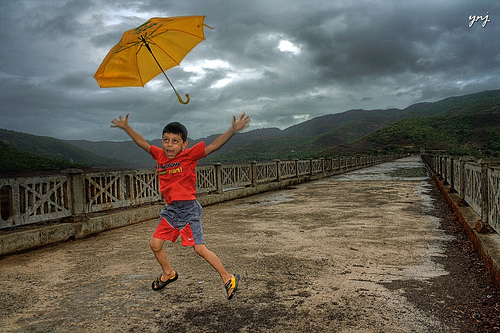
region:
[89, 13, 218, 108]
Yellow umbrella in the air.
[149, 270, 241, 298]
Grey and yellow sandals.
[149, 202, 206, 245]
Grey and red shorts.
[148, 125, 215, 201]
Boy wearing a red t-shirt with a design on the front.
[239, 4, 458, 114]
Ominous dark clouds.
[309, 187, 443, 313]
Rough well-traveled road?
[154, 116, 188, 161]
Safety railing near road.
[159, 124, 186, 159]
A young boy showing lots of emotions.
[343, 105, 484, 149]
Mountians and rolling hills.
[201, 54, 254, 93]
Sunlight peeping through clouds.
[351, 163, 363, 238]
part of a path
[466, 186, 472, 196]
part of a rail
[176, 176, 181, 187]
part of a shirt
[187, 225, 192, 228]
part of a short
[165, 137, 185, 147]
face of a boy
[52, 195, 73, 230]
part of a fence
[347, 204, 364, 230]
part of a bridge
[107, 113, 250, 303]
a boy jumping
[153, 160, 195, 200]
boy wearing a red shirt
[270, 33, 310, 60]
light in the sky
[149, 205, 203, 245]
grey and red shorts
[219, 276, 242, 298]
boy is wearing yellow sandals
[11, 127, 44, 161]
grass on the mountain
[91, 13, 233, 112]
an umbrealla in the sky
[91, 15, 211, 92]
the umbrealla is yellow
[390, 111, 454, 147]
a mountain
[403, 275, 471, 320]
dirt on the ground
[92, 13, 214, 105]
bright yellow child sized umbrella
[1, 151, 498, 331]
long concrete bridge walkway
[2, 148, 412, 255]
slightly ornate safety fence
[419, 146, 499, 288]
slightly ornate safety fence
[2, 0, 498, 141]
very dark and stormy sky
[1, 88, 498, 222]
tree and grass covered hills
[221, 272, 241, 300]
yellow and black sandal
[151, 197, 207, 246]
grey and red kids shorts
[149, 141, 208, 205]
red shirt with printed logo on it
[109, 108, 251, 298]
little boy jumping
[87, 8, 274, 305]
boy throwing an umbrella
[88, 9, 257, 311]
a yellow umbrella over a boy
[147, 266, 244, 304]
yellow open shoes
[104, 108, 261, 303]
boy has red shirt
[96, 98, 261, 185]
two hands up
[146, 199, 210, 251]
a blue and red shorts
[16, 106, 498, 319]
a boy on a bridge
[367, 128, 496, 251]
rails on right side of bridge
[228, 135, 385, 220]
rails on left side of bridge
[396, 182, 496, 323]
gravel on side a bridge